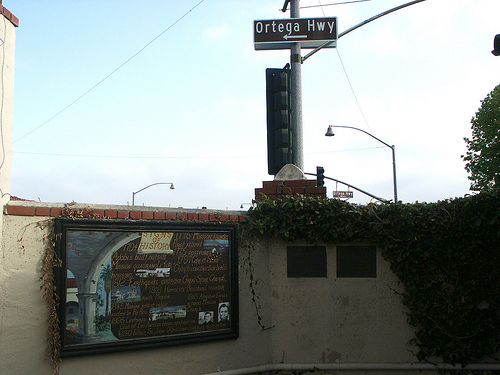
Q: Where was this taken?
A: Near Ortega Highway.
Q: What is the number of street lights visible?
A: Three.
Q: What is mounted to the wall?
A: A picture.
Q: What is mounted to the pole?
A: Traffic signal.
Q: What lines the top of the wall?
A: Red brick.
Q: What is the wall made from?
A: Stucco.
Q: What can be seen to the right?
A: Trees.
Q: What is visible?
A: A road sign.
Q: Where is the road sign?
A: Visible.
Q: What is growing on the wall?
A: Ivy.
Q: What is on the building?
A: Windows.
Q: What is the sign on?
A: Metal post.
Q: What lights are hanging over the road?
A: Street lights.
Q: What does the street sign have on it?
A: An arrow.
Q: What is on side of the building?
A: A painting.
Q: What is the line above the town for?
A: Power line.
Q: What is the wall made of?
A: Concrete.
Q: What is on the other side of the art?
A: Dead ivy.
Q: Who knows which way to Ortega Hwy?
A: The sign reader.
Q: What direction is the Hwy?
A: To the left.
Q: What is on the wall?
A: Signs of History.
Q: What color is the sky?
A: Bright blue with some clouds.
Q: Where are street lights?
A: Along the street.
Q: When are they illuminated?
A: At dusk.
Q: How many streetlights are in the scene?
A: At least 3.